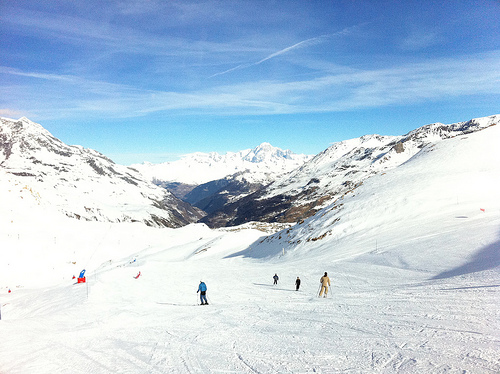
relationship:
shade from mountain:
[154, 172, 343, 262] [2, 116, 499, 249]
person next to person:
[273, 273, 280, 286] [294, 277, 302, 293]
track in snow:
[228, 337, 257, 372] [1, 103, 497, 372]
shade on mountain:
[154, 172, 343, 262] [2, 116, 499, 249]